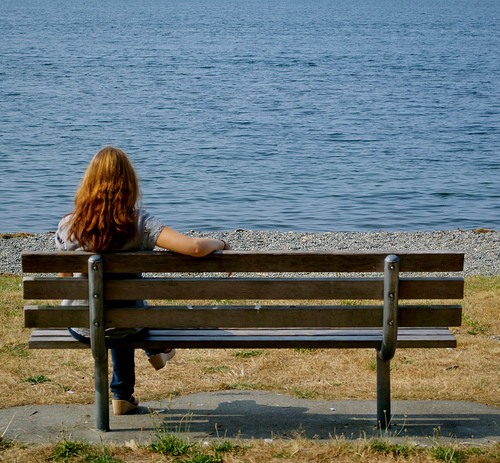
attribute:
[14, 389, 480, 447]
slab — concrete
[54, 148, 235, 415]
woman — sitting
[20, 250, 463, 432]
bench — brown, silver, large, wooden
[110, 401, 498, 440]
shadow — dark grey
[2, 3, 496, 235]
water — calm, blue, rippling, large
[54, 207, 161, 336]
top — gray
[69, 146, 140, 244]
hair — long, brown, reddish tinted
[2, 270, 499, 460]
grass — green, brown, small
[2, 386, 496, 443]
slate granite — gray